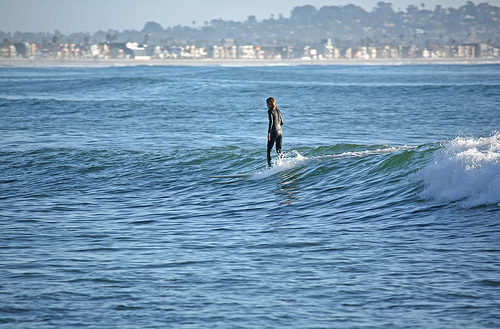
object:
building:
[9, 47, 19, 58]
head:
[266, 97, 277, 107]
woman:
[266, 97, 285, 168]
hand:
[267, 132, 272, 141]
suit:
[267, 107, 283, 169]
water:
[2, 71, 498, 329]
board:
[212, 173, 260, 181]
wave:
[283, 140, 499, 208]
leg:
[264, 135, 276, 166]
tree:
[248, 17, 258, 47]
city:
[43, 39, 499, 60]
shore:
[6, 58, 499, 65]